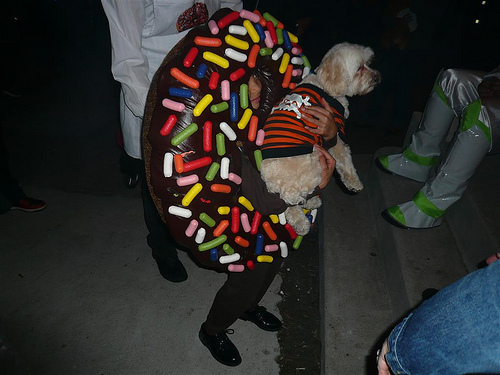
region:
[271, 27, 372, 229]
this is a dog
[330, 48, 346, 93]
the dog is brown in color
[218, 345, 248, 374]
this is a shoe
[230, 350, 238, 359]
the shoe is black in color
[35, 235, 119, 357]
this is the floor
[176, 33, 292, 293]
this is a lady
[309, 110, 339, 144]
the lady is light skinned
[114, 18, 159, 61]
this is a uproan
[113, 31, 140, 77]
the uproan is white in color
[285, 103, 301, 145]
this is a t shirt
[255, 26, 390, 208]
A dog with a Halloween costume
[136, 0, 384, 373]
A person dressed as a donut for Halloween with a dog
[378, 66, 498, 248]
Person wearing plastic footwear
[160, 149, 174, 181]
White confection on a chocolate doughut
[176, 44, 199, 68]
Red confection on a chocolate doughnut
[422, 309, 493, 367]
A denim surface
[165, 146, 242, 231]
Colored sprinkles on a chocolate donut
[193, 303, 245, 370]
A person's right black leather shoe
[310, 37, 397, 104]
A dogs head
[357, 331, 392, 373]
Ring on a finger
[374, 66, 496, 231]
two legs in costume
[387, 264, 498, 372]
leg of blue jeans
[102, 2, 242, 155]
person in white shirt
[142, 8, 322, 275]
person in donut costume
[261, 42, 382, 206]
dog being held in hands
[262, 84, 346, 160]
striped sweater on dog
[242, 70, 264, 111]
face of person in hole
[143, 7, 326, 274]
sprinkles on donut costume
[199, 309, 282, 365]
black shoes on feet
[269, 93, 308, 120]
white emblem on shirt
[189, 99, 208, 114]
yellow sprinkle on costume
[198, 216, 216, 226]
green sprinkle on costume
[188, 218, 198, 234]
pink sprinkle on costume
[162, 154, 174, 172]
white sprinkle on costume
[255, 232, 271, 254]
blue sprinkle on costume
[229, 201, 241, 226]
red sprinkle on costume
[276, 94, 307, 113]
white skull on dog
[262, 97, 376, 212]
boy carrying small dog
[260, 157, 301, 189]
tan fur on dog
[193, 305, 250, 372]
black shoe on boy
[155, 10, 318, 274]
inflatable tube looking like a donut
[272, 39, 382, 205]
a dog wearing a sweater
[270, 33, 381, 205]
a brown and white dog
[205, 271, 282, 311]
a person wearing black pants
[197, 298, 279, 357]
a person wearing black shoes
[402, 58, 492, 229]
a person wearing a costume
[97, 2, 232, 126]
a person wearing a white shirt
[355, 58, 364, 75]
the right eye of a dog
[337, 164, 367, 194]
the paw of a dog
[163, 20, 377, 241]
a person holding a dog